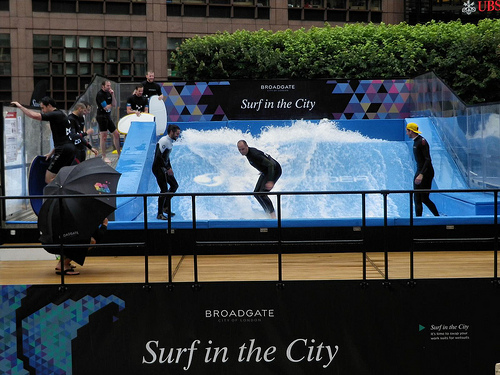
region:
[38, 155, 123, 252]
the umbrella is black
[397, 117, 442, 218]
man wears black suit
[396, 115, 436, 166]
man has yellow cap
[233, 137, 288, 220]
the man is crouched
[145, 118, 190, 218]
man has white and black suit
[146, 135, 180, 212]
black and white wetsuit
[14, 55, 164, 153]
people wearing black cloths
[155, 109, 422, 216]
water in a fountain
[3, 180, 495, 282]
the rail is black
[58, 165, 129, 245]
a black unbrella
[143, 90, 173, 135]
a white surfboard on the stage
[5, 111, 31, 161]
a sign on the wall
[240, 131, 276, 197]
man wearing a wetsuit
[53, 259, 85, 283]
a pair of sandals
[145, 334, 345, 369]
surf in the city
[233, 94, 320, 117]
surf in the city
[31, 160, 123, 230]
black umbrella with logo on it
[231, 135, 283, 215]
person surfing on artificial wave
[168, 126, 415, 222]
wave made artificially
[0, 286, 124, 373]
blue wave logo in wall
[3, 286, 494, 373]
black and blue wall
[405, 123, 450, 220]
person wearing black suit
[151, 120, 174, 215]
person in grey and white suit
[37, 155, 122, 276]
someone holding a black umbrella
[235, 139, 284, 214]
man in black wetsuit in sirf simulator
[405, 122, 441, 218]
man in black wetsuit and yellow hat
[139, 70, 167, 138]
man in black wetsuit holding white surfboard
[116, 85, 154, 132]
man in black wetsuit holding white surfboard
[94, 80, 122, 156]
man standing in black wetsuit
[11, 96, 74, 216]
man leaning against fence with blue surfboard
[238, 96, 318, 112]
name of machine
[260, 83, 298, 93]
name of company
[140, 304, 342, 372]
identification of machine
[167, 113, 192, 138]
head of a person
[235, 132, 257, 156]
head of a person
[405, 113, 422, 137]
head of a person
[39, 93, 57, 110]
head of a person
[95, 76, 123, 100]
head of a person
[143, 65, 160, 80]
head of a person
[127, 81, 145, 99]
head of a person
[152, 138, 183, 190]
arm of a person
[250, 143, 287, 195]
arm of a person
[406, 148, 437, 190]
arm of a person